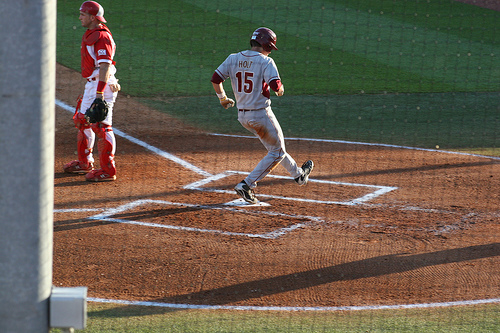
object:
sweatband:
[96, 81, 106, 93]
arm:
[95, 33, 110, 99]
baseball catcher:
[63, 0, 121, 181]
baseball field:
[0, 0, 499, 331]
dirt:
[53, 134, 499, 288]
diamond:
[56, 94, 500, 310]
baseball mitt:
[86, 97, 107, 123]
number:
[231, 70, 255, 96]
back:
[230, 51, 269, 108]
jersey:
[210, 53, 282, 111]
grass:
[55, 0, 500, 149]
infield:
[54, 0, 497, 238]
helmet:
[247, 27, 281, 52]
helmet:
[71, 1, 117, 25]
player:
[209, 24, 316, 204]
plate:
[223, 196, 278, 208]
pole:
[0, 1, 56, 331]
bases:
[222, 194, 273, 208]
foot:
[231, 181, 258, 203]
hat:
[78, 0, 112, 25]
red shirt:
[78, 27, 115, 79]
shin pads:
[71, 108, 115, 172]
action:
[58, 0, 316, 205]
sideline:
[55, 94, 215, 179]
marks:
[57, 95, 500, 314]